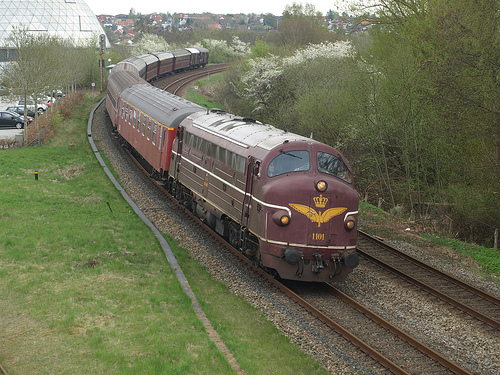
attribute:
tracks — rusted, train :
[335, 254, 483, 367]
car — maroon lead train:
[177, 111, 368, 282]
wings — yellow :
[294, 191, 344, 234]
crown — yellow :
[282, 190, 352, 239]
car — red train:
[166, 108, 370, 293]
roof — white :
[186, 46, 200, 56]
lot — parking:
[6, 75, 60, 147]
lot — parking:
[4, 87, 53, 129]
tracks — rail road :
[332, 269, 484, 372]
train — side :
[100, 29, 368, 287]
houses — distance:
[109, 8, 289, 39]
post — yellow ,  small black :
[88, 53, 109, 92]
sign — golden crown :
[288, 182, 355, 244]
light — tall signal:
[88, 39, 115, 109]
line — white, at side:
[155, 137, 304, 225]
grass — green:
[187, 229, 325, 373]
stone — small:
[373, 265, 472, 351]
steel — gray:
[71, 69, 249, 373]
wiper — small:
[274, 138, 311, 166]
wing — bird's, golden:
[280, 191, 312, 220]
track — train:
[307, 220, 492, 367]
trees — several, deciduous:
[254, 43, 495, 250]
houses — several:
[97, 6, 232, 52]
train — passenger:
[74, 23, 370, 307]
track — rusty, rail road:
[275, 213, 497, 369]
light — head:
[312, 173, 332, 195]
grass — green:
[3, 119, 133, 372]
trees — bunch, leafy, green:
[294, 2, 495, 225]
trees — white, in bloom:
[245, 28, 385, 98]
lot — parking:
[0, 53, 90, 133]